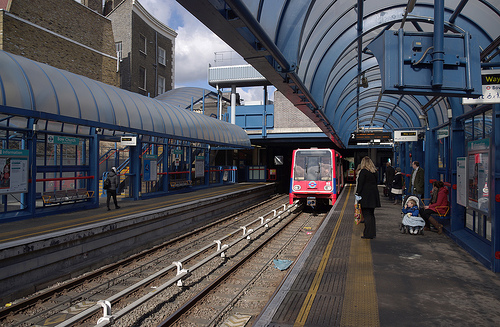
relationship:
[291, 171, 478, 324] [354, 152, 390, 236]
ground under woman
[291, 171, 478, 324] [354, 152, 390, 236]
ground below woman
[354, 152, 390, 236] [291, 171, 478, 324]
woman above ground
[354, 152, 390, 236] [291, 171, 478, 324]
woman on ground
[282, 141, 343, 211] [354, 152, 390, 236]
train beside woman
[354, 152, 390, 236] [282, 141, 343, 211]
woman beside train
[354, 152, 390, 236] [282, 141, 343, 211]
woman near train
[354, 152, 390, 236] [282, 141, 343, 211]
woman next to train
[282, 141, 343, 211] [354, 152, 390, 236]
train near woman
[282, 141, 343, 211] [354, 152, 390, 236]
train next to woman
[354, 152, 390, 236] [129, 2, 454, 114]
woman under sky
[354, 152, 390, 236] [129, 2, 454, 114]
woman below sky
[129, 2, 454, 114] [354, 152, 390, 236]
sky above woman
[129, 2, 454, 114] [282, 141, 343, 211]
sky above train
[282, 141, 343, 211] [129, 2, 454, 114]
train below sky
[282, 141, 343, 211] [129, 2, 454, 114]
train under sky